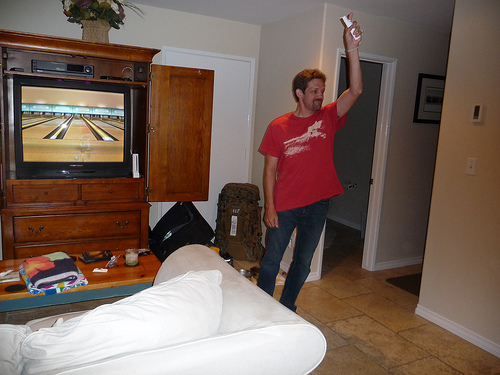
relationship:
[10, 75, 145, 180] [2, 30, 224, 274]
television in cabinet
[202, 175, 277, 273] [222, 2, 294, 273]
suitcase in corner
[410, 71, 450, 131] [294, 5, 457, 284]
picture on wall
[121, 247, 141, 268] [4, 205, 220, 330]
candle on table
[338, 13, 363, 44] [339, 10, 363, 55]
wii remote in hand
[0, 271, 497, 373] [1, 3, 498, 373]
floor in room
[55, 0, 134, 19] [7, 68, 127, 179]
flowers above tv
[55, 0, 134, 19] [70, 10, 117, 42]
flowers in pot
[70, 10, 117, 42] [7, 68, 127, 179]
pot above tv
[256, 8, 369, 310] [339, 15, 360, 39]
man holding up controller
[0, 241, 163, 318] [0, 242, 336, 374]
table in front of couch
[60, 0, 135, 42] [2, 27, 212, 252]
flowers on top of cabinet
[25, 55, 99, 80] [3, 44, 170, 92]
player on cabinet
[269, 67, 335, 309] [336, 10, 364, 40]
he holding remote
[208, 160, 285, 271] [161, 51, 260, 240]
luggage against door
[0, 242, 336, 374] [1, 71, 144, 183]
couch in front of tv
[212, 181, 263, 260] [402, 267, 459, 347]
item in corner